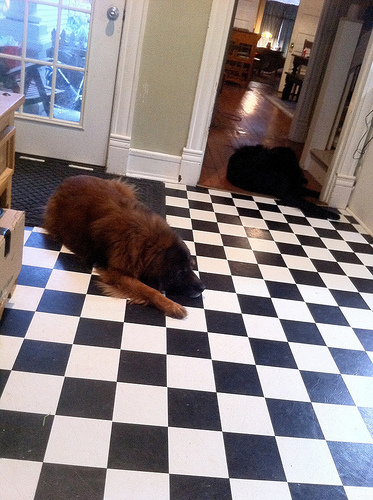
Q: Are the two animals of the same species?
A: Yes, all the animals are dogs.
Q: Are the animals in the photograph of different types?
A: No, all the animals are dogs.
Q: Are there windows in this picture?
A: Yes, there is a window.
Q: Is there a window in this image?
A: Yes, there is a window.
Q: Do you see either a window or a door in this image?
A: Yes, there is a window.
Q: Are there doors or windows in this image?
A: Yes, there is a window.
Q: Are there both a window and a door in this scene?
A: Yes, there are both a window and a door.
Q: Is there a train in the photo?
A: No, there are no trains.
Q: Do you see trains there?
A: No, there are no trains.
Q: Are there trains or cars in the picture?
A: No, there are no trains or cars.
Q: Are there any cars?
A: No, there are no cars.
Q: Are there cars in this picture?
A: No, there are no cars.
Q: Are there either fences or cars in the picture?
A: No, there are no cars or fences.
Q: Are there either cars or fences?
A: No, there are no cars or fences.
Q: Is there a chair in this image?
A: Yes, there is a chair.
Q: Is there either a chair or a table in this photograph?
A: Yes, there is a chair.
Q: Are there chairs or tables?
A: Yes, there is a chair.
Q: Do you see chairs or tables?
A: Yes, there is a chair.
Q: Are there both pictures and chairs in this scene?
A: No, there is a chair but no pictures.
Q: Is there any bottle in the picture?
A: No, there are no bottles.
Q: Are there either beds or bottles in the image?
A: No, there are no bottles or beds.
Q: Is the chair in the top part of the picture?
A: Yes, the chair is in the top of the image.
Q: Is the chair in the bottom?
A: No, the chair is in the top of the image.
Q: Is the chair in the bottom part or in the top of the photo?
A: The chair is in the top of the image.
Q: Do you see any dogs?
A: Yes, there is a dog.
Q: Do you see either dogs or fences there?
A: Yes, there is a dog.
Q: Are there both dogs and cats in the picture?
A: No, there is a dog but no cats.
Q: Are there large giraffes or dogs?
A: Yes, there is a large dog.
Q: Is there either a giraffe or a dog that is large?
A: Yes, the dog is large.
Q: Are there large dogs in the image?
A: Yes, there is a large dog.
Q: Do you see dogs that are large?
A: Yes, there is a dog that is large.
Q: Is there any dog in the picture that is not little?
A: Yes, there is a large dog.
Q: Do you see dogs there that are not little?
A: Yes, there is a large dog.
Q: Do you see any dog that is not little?
A: Yes, there is a large dog.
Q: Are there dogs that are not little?
A: Yes, there is a large dog.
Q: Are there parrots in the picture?
A: No, there are no parrots.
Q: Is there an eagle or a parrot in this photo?
A: No, there are no parrots or eagles.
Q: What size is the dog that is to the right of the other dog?
A: The dog is large.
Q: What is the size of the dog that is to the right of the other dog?
A: The dog is large.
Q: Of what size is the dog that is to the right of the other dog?
A: The dog is large.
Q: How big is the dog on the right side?
A: The dog is large.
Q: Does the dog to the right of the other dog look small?
A: No, the dog is large.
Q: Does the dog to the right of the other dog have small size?
A: No, the dog is large.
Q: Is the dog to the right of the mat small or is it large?
A: The dog is large.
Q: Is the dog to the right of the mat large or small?
A: The dog is large.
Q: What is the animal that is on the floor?
A: The animal is a dog.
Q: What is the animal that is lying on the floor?
A: The animal is a dog.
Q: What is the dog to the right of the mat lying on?
A: The dog is lying on the floor.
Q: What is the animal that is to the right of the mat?
A: The animal is a dog.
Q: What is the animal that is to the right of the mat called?
A: The animal is a dog.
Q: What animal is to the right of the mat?
A: The animal is a dog.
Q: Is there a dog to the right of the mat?
A: Yes, there is a dog to the right of the mat.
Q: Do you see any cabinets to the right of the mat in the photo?
A: No, there is a dog to the right of the mat.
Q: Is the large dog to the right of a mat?
A: Yes, the dog is to the right of a mat.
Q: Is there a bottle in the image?
A: No, there are no bottles.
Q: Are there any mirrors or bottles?
A: No, there are no bottles or mirrors.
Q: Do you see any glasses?
A: No, there are no glasses.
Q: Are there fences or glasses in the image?
A: No, there are no glasses or fences.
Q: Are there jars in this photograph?
A: No, there are no jars.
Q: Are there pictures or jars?
A: No, there are no jars or pictures.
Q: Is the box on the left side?
A: Yes, the box is on the left of the image.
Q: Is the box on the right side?
A: No, the box is on the left of the image.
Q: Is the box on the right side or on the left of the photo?
A: The box is on the left of the image.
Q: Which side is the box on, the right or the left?
A: The box is on the left of the image.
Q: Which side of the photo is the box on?
A: The box is on the left of the image.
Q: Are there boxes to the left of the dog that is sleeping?
A: Yes, there is a box to the left of the dog.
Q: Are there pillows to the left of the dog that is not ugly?
A: No, there is a box to the left of the dog.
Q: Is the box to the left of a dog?
A: Yes, the box is to the left of a dog.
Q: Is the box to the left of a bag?
A: No, the box is to the left of a dog.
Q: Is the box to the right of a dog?
A: No, the box is to the left of a dog.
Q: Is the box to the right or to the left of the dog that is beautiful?
A: The box is to the left of the dog.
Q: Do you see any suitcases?
A: No, there are no suitcases.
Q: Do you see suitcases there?
A: No, there are no suitcases.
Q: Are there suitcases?
A: No, there are no suitcases.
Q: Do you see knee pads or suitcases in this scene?
A: No, there are no suitcases or knee pads.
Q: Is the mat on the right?
A: No, the mat is on the left of the image.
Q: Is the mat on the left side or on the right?
A: The mat is on the left of the image.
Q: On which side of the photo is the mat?
A: The mat is on the left of the image.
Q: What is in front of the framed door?
A: The mat is in front of the door.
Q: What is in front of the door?
A: The mat is in front of the door.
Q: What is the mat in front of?
A: The mat is in front of the door.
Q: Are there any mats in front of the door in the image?
A: Yes, there is a mat in front of the door.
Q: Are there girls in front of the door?
A: No, there is a mat in front of the door.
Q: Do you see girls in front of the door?
A: No, there is a mat in front of the door.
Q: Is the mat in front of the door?
A: Yes, the mat is in front of the door.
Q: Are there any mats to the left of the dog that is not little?
A: Yes, there is a mat to the left of the dog.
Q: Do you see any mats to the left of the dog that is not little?
A: Yes, there is a mat to the left of the dog.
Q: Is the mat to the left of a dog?
A: Yes, the mat is to the left of a dog.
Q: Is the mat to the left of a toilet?
A: No, the mat is to the left of a dog.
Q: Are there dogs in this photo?
A: Yes, there is a dog.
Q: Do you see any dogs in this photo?
A: Yes, there is a dog.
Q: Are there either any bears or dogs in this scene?
A: Yes, there is a dog.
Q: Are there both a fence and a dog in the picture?
A: No, there is a dog but no fences.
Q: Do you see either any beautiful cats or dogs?
A: Yes, there is a beautiful dog.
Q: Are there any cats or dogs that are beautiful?
A: Yes, the dog is beautiful.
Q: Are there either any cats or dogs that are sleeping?
A: Yes, the dog is sleeping.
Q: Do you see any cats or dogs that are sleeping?
A: Yes, the dog is sleeping.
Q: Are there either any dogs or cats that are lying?
A: Yes, the dog is lying.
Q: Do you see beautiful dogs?
A: Yes, there is a beautiful dog.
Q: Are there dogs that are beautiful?
A: Yes, there is a dog that is beautiful.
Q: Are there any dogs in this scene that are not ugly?
A: Yes, there is an beautiful dog.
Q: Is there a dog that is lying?
A: Yes, there is a dog that is lying.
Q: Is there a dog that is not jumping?
A: Yes, there is a dog that is lying.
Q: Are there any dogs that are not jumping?
A: Yes, there is a dog that is lying.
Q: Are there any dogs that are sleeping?
A: Yes, there is a dog that is sleeping.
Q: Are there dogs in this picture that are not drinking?
A: Yes, there is a dog that is sleeping.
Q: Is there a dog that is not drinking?
A: Yes, there is a dog that is sleeping.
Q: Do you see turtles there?
A: No, there are no turtles.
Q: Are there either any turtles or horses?
A: No, there are no turtles or horses.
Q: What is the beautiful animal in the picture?
A: The animal is a dog.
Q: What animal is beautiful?
A: The animal is a dog.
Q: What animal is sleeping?
A: The animal is a dog.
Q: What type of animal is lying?
A: The animal is a dog.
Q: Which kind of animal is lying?
A: The animal is a dog.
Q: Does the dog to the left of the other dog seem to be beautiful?
A: Yes, the dog is beautiful.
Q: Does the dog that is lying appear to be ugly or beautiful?
A: The dog is beautiful.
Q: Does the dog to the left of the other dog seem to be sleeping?
A: Yes, the dog is sleeping.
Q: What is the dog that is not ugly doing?
A: The dog is sleeping.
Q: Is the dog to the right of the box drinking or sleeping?
A: The dog is sleeping.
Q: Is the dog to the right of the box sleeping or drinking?
A: The dog is sleeping.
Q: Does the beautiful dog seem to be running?
A: No, the dog is lying.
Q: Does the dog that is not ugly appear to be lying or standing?
A: The dog is lying.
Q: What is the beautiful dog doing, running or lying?
A: The dog is lying.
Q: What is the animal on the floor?
A: The animal is a dog.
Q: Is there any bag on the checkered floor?
A: No, there is a dog on the floor.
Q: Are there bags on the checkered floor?
A: No, there is a dog on the floor.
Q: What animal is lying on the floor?
A: The dog is lying on the floor.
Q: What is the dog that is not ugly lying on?
A: The dog is lying on the floor.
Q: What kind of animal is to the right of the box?
A: The animal is a dog.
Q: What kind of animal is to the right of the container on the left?
A: The animal is a dog.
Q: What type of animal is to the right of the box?
A: The animal is a dog.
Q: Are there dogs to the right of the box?
A: Yes, there is a dog to the right of the box.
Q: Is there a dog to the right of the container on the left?
A: Yes, there is a dog to the right of the box.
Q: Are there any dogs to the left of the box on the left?
A: No, the dog is to the right of the box.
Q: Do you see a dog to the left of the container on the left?
A: No, the dog is to the right of the box.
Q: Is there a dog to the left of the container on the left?
A: No, the dog is to the right of the box.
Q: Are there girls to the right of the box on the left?
A: No, there is a dog to the right of the box.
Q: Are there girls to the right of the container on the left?
A: No, there is a dog to the right of the box.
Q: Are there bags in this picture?
A: No, there are no bags.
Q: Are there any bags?
A: No, there are no bags.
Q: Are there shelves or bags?
A: No, there are no bags or shelves.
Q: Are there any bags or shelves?
A: No, there are no bags or shelves.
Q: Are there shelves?
A: No, there are no shelves.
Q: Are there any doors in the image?
A: Yes, there is a door.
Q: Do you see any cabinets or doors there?
A: Yes, there is a door.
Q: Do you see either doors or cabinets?
A: Yes, there is a door.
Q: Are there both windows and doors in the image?
A: Yes, there are both a door and windows.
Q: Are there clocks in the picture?
A: No, there are no clocks.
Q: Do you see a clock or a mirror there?
A: No, there are no clocks or mirrors.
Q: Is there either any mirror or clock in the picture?
A: No, there are no clocks or mirrors.